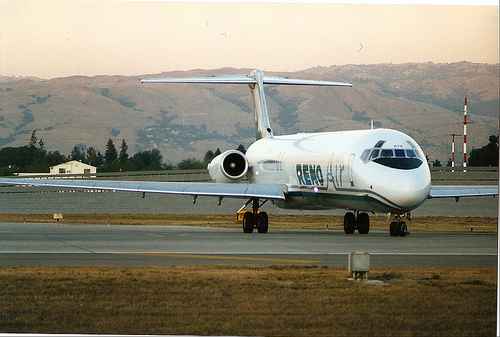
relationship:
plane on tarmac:
[14, 66, 498, 242] [0, 222, 496, 267]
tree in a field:
[116, 135, 131, 170] [102, 142, 203, 176]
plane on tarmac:
[0, 69, 499, 238] [2, 219, 494, 268]